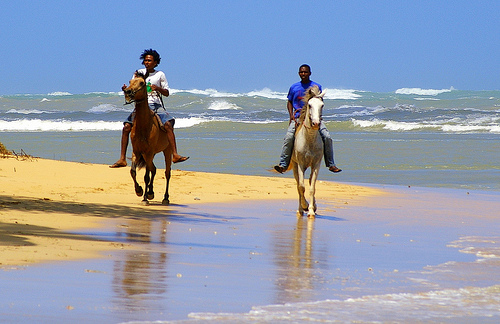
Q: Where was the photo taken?
A: It was taken at the beach.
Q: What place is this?
A: It is a beach.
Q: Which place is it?
A: It is a beach.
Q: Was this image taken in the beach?
A: Yes, it was taken in the beach.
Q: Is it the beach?
A: Yes, it is the beach.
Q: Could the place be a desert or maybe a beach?
A: It is a beach.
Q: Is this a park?
A: No, it is a beach.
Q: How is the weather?
A: It is clear.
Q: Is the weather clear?
A: Yes, it is clear.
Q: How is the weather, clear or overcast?
A: It is clear.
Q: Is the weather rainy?
A: No, it is clear.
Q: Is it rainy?
A: No, it is clear.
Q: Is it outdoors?
A: Yes, it is outdoors.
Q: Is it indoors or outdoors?
A: It is outdoors.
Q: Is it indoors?
A: No, it is outdoors.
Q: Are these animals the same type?
A: Yes, all the animals are horses.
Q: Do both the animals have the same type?
A: Yes, all the animals are horses.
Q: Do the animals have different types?
A: No, all the animals are horses.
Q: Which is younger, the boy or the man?
A: The boy is younger than the man.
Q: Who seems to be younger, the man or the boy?
A: The boy is younger than the man.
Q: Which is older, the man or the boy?
A: The man is older than the boy.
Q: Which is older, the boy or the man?
A: The man is older than the boy.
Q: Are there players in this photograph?
A: No, there are no players.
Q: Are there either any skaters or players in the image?
A: No, there are no players or skaters.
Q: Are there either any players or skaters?
A: No, there are no players or skaters.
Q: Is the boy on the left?
A: Yes, the boy is on the left of the image.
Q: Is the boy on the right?
A: No, the boy is on the left of the image.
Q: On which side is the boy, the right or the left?
A: The boy is on the left of the image.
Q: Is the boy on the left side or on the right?
A: The boy is on the left of the image.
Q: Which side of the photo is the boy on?
A: The boy is on the left of the image.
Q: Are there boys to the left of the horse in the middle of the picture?
A: Yes, there is a boy to the left of the horse.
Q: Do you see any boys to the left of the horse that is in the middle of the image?
A: Yes, there is a boy to the left of the horse.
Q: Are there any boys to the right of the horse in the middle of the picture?
A: No, the boy is to the left of the horse.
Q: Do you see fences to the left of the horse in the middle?
A: No, there is a boy to the left of the horse.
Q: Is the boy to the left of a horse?
A: Yes, the boy is to the left of a horse.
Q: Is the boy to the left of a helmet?
A: No, the boy is to the left of a horse.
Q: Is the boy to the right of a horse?
A: No, the boy is to the left of a horse.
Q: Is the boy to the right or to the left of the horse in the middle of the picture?
A: The boy is to the left of the horse.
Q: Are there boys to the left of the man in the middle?
A: Yes, there is a boy to the left of the man.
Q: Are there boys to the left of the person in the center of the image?
A: Yes, there is a boy to the left of the man.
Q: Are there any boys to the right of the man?
A: No, the boy is to the left of the man.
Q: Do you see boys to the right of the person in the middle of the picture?
A: No, the boy is to the left of the man.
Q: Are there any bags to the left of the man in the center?
A: No, there is a boy to the left of the man.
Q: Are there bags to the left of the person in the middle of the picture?
A: No, there is a boy to the left of the man.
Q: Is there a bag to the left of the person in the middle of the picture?
A: No, there is a boy to the left of the man.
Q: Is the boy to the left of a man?
A: Yes, the boy is to the left of a man.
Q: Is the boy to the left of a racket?
A: No, the boy is to the left of a man.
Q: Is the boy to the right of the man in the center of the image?
A: No, the boy is to the left of the man.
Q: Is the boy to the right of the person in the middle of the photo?
A: No, the boy is to the left of the man.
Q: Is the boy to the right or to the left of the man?
A: The boy is to the left of the man.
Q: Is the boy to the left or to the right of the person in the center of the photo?
A: The boy is to the left of the man.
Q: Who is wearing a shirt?
A: The boy is wearing a shirt.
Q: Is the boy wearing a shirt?
A: Yes, the boy is wearing a shirt.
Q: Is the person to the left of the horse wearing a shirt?
A: Yes, the boy is wearing a shirt.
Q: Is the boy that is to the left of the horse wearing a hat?
A: No, the boy is wearing a shirt.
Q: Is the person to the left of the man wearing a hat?
A: No, the boy is wearing a shirt.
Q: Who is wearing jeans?
A: The boy is wearing jeans.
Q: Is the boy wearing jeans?
A: Yes, the boy is wearing jeans.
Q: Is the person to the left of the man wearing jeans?
A: Yes, the boy is wearing jeans.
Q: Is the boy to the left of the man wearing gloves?
A: No, the boy is wearing jeans.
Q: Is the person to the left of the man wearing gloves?
A: No, the boy is wearing jeans.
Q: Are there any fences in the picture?
A: No, there are no fences.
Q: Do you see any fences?
A: No, there are no fences.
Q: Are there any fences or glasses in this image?
A: No, there are no fences or glasses.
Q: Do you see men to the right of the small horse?
A: Yes, there is a man to the right of the horse.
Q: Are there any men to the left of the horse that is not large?
A: No, the man is to the right of the horse.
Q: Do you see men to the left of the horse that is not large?
A: No, the man is to the right of the horse.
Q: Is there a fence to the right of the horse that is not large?
A: No, there is a man to the right of the horse.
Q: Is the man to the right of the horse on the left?
A: Yes, the man is to the right of the horse.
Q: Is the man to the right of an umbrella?
A: No, the man is to the right of the horse.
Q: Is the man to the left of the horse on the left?
A: No, the man is to the right of the horse.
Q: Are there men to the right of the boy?
A: Yes, there is a man to the right of the boy.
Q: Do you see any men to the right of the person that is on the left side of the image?
A: Yes, there is a man to the right of the boy.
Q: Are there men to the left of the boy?
A: No, the man is to the right of the boy.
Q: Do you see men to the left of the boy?
A: No, the man is to the right of the boy.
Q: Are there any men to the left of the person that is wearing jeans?
A: No, the man is to the right of the boy.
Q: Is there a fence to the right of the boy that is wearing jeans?
A: No, there is a man to the right of the boy.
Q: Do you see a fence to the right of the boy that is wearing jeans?
A: No, there is a man to the right of the boy.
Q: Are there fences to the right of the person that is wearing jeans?
A: No, there is a man to the right of the boy.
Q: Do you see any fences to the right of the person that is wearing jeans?
A: No, there is a man to the right of the boy.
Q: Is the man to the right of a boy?
A: Yes, the man is to the right of a boy.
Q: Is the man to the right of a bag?
A: No, the man is to the right of a boy.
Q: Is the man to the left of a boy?
A: No, the man is to the right of a boy.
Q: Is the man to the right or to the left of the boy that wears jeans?
A: The man is to the right of the boy.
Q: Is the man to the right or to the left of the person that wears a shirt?
A: The man is to the right of the boy.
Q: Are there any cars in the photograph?
A: No, there are no cars.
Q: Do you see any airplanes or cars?
A: No, there are no cars or airplanes.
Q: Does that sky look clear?
A: Yes, the sky is clear.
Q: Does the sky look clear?
A: Yes, the sky is clear.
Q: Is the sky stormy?
A: No, the sky is clear.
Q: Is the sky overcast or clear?
A: The sky is clear.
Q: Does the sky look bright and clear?
A: Yes, the sky is bright and clear.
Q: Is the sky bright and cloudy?
A: No, the sky is bright but clear.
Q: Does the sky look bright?
A: Yes, the sky is bright.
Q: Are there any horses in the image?
A: Yes, there is a horse.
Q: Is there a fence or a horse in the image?
A: Yes, there is a horse.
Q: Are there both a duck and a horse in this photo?
A: No, there is a horse but no ducks.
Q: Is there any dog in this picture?
A: No, there are no dogs.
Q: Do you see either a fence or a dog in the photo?
A: No, there are no dogs or fences.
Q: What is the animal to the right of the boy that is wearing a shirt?
A: The animal is a horse.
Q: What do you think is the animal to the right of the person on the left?
A: The animal is a horse.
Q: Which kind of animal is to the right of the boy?
A: The animal is a horse.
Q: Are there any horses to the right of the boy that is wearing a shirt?
A: Yes, there is a horse to the right of the boy.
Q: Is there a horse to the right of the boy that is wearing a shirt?
A: Yes, there is a horse to the right of the boy.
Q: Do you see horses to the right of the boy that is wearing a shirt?
A: Yes, there is a horse to the right of the boy.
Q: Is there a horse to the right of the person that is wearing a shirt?
A: Yes, there is a horse to the right of the boy.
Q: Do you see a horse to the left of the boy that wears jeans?
A: No, the horse is to the right of the boy.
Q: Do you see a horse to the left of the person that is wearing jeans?
A: No, the horse is to the right of the boy.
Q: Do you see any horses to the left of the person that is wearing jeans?
A: No, the horse is to the right of the boy.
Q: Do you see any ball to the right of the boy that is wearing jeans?
A: No, there is a horse to the right of the boy.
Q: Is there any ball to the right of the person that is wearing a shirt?
A: No, there is a horse to the right of the boy.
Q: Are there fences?
A: No, there are no fences.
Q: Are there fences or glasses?
A: No, there are no fences or glasses.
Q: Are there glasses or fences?
A: No, there are no fences or glasses.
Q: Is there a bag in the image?
A: No, there are no bags.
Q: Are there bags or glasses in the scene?
A: No, there are no bags or glasses.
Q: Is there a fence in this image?
A: No, there are no fences.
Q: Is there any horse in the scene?
A: Yes, there is a horse.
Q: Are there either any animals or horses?
A: Yes, there is a horse.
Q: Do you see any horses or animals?
A: Yes, there is a horse.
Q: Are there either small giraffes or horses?
A: Yes, there is a small horse.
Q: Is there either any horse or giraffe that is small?
A: Yes, the horse is small.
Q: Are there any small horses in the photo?
A: Yes, there is a small horse.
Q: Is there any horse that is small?
A: Yes, there is a horse that is small.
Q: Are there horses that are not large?
A: Yes, there is a small horse.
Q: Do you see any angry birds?
A: No, there are no angry birds.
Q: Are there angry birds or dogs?
A: No, there are no angry birds or dogs.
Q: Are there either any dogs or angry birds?
A: No, there are no angry birds or dogs.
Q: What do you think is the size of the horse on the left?
A: The horse is small.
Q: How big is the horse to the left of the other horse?
A: The horse is small.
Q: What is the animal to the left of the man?
A: The animal is a horse.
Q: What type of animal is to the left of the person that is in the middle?
A: The animal is a horse.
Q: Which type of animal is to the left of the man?
A: The animal is a horse.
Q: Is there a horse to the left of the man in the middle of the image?
A: Yes, there is a horse to the left of the man.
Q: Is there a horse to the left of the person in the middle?
A: Yes, there is a horse to the left of the man.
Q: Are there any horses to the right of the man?
A: No, the horse is to the left of the man.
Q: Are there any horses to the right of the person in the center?
A: No, the horse is to the left of the man.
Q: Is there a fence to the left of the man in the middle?
A: No, there is a horse to the left of the man.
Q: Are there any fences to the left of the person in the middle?
A: No, there is a horse to the left of the man.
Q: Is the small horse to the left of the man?
A: Yes, the horse is to the left of the man.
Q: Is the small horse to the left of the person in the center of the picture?
A: Yes, the horse is to the left of the man.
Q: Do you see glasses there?
A: No, there are no glasses.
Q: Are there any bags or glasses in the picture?
A: No, there are no glasses or bags.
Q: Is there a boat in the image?
A: No, there are no boats.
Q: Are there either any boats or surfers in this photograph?
A: No, there are no boats or surfers.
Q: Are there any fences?
A: No, there are no fences.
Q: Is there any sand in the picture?
A: Yes, there is sand.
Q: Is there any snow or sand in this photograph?
A: Yes, there is sand.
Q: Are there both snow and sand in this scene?
A: No, there is sand but no snow.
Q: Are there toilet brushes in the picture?
A: No, there are no toilet brushes.